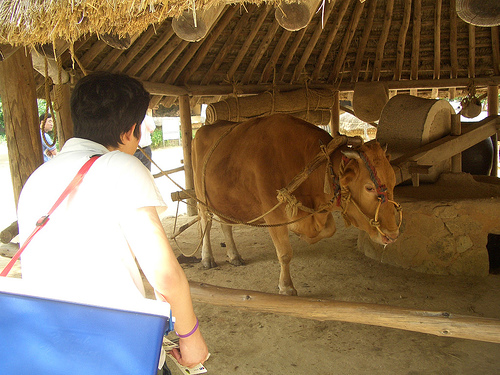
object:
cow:
[190, 114, 399, 295]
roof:
[2, 0, 500, 98]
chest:
[288, 202, 337, 245]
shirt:
[18, 138, 172, 299]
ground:
[0, 145, 500, 372]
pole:
[190, 283, 499, 345]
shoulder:
[88, 152, 144, 196]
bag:
[460, 86, 482, 118]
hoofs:
[278, 283, 296, 297]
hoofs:
[202, 255, 218, 269]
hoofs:
[228, 253, 246, 267]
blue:
[63, 321, 158, 358]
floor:
[348, 247, 436, 296]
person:
[18, 72, 210, 374]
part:
[165, 247, 187, 277]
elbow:
[153, 264, 186, 298]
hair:
[69, 71, 154, 151]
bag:
[1, 155, 172, 373]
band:
[175, 317, 200, 338]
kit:
[0, 290, 170, 374]